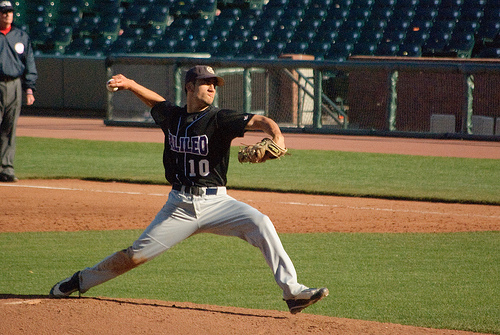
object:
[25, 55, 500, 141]
fence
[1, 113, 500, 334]
field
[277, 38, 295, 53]
chair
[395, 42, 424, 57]
stadium seats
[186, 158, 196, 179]
number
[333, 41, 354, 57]
chair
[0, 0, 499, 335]
stadium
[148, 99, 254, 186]
shirt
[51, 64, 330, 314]
man